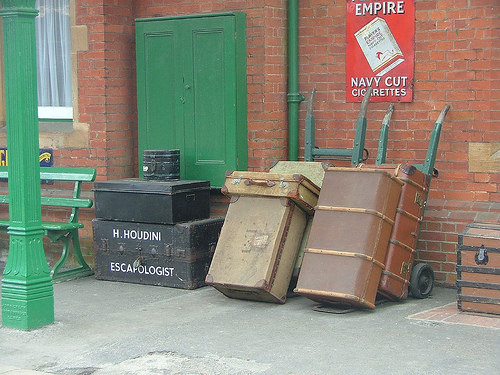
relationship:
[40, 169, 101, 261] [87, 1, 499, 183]
bench by building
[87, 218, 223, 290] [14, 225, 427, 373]
black case on ground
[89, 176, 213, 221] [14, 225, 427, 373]
black case on ground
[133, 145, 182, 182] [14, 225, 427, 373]
black case on ground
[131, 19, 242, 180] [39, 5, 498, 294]
doors on building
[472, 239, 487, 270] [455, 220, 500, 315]
lock on case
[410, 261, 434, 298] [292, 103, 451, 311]
handtruck wheel on cart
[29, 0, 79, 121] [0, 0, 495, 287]
window on building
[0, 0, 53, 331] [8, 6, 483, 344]
lamppost by building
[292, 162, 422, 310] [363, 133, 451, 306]
cases on hand truck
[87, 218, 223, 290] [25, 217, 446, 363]
black case on ground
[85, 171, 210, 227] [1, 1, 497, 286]
case against wall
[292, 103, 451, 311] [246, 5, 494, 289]
cart leaning against wall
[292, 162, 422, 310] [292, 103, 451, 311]
cases on cart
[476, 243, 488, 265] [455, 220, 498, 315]
lock on case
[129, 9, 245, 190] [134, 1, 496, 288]
cabinet on wall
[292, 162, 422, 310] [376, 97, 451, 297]
cases on cart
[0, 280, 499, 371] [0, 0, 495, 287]
ground outside building